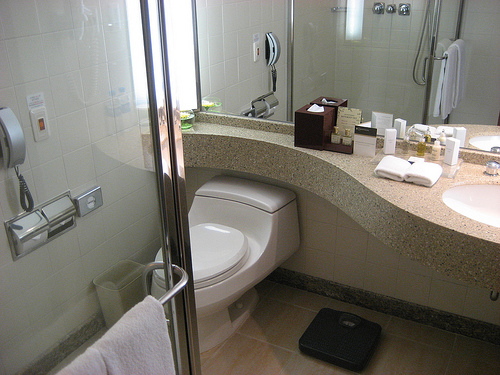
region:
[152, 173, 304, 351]
white porcelain toilet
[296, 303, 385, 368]
black scales on the floor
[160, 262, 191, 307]
silver towel rack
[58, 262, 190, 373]
silver towel rack with two towels hanging on it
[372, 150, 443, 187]
two folded white towels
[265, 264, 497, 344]
gray, black, and white base board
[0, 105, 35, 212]
a silver colored telephone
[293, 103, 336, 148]
a brown tissue box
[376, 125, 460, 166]
various perfumes on the sink counter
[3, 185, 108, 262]
silver toilet paper and tissue holders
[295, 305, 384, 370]
Black analog weight scale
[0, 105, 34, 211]
Silver corded telephone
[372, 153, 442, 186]
Two folded white towels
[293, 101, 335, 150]
Brown tissue box with white tissue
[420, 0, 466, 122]
Shower door with two bath towels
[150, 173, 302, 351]
Closed white toilet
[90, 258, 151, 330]
Empty white trashcan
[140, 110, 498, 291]
Speckled pattern bathroom counter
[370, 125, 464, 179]
Soaps and hair products on a glass plate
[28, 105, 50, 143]
Emergency shower button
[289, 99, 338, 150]
Tissue box is brown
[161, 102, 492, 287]
The counter is beige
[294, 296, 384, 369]
The scale is black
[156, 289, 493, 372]
Tiles on the ground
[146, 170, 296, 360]
The toilet is white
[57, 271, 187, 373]
White towels hanging from railing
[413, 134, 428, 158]
Yellow bottle with white top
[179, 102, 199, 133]
Glass bowl with green liquid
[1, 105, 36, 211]
The phone is silver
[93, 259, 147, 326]
Trash can is next to toilet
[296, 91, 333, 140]
Box of napkins on a sink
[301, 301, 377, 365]
Scale on a bathroom floor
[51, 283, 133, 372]
towel on a bathroom bar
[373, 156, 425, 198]
Towels on the bathroom sink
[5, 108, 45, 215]
Intercom on the wall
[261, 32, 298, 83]
Phone in the mirror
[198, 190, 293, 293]
white toilet bowl in the bathroom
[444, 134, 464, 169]
box of perfume in bathroom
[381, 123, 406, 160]
Lotion on the sink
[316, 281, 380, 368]
Black scale in the bathroom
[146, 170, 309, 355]
trendy white toilet bowl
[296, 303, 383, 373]
black bathroom weight scale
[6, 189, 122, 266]
built in toilet paper and tissue holders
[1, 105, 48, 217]
bathroom cord phone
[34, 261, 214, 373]
white towels hanging on shower door handle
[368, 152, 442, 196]
folded white hand towels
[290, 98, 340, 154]
brown decorative tissue box cover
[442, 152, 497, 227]
built in bathroom sink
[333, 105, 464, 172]
complimentary travel size toiletries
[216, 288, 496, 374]
light pink bathroom tiles